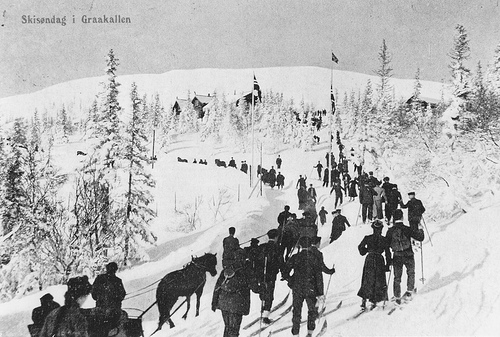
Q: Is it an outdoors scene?
A: Yes, it is outdoors.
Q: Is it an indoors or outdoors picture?
A: It is outdoors.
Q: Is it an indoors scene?
A: No, it is outdoors.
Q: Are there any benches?
A: No, there are no benches.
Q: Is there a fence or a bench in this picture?
A: No, there are no benches or fences.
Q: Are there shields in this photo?
A: No, there are no shields.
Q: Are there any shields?
A: No, there are no shields.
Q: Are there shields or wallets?
A: No, there are no shields or wallets.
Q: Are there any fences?
A: No, there are no fences.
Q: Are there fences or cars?
A: No, there are no fences or cars.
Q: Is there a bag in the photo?
A: Yes, there is a bag.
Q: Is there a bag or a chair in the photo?
A: Yes, there is a bag.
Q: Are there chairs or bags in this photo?
A: Yes, there is a bag.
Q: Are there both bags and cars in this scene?
A: No, there is a bag but no cars.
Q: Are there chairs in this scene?
A: No, there are no chairs.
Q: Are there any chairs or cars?
A: No, there are no chairs or cars.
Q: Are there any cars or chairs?
A: No, there are no chairs or cars.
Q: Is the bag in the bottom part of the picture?
A: Yes, the bag is in the bottom of the image.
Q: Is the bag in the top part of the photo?
A: No, the bag is in the bottom of the image.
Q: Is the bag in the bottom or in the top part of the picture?
A: The bag is in the bottom of the image.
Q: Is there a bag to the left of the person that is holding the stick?
A: Yes, there is a bag to the left of the person.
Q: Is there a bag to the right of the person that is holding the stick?
A: No, the bag is to the left of the person.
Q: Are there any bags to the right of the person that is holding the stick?
A: No, the bag is to the left of the person.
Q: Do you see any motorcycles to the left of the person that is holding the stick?
A: No, there is a bag to the left of the person.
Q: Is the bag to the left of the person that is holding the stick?
A: Yes, the bag is to the left of the person.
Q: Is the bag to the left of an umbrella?
A: No, the bag is to the left of the person.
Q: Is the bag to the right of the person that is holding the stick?
A: No, the bag is to the left of the person.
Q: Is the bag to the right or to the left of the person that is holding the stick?
A: The bag is to the left of the person.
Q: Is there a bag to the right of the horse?
A: Yes, there is a bag to the right of the horse.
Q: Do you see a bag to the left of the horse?
A: No, the bag is to the right of the horse.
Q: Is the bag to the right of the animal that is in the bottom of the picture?
A: Yes, the bag is to the right of the horse.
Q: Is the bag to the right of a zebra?
A: No, the bag is to the right of the horse.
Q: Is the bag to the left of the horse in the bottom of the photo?
A: No, the bag is to the right of the horse.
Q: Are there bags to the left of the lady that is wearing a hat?
A: Yes, there is a bag to the left of the lady.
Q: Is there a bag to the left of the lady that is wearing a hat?
A: Yes, there is a bag to the left of the lady.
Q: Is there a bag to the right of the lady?
A: No, the bag is to the left of the lady.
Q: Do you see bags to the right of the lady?
A: No, the bag is to the left of the lady.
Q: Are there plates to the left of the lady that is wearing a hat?
A: No, there is a bag to the left of the lady.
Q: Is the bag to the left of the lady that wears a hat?
A: Yes, the bag is to the left of the lady.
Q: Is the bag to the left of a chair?
A: No, the bag is to the left of the lady.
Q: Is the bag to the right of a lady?
A: No, the bag is to the left of a lady.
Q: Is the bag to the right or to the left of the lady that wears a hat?
A: The bag is to the left of the lady.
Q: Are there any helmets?
A: No, there are no helmets.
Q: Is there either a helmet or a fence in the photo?
A: No, there are no helmets or fences.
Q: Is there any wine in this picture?
A: No, there is no wine.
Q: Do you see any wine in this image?
A: No, there is no wine.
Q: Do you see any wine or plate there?
A: No, there are no wine or plates.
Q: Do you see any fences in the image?
A: No, there are no fences.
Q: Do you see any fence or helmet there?
A: No, there are no fences or helmets.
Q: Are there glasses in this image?
A: No, there are no glasses.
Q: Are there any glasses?
A: No, there are no glasses.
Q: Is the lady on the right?
A: Yes, the lady is on the right of the image.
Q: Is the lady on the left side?
A: No, the lady is on the right of the image.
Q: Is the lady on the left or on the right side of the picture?
A: The lady is on the right of the image.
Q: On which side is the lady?
A: The lady is on the right of the image.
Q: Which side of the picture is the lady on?
A: The lady is on the right of the image.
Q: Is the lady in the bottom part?
A: Yes, the lady is in the bottom of the image.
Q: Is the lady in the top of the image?
A: No, the lady is in the bottom of the image.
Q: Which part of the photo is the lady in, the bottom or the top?
A: The lady is in the bottom of the image.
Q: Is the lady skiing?
A: Yes, the lady is skiing.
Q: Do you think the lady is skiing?
A: Yes, the lady is skiing.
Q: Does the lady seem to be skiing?
A: Yes, the lady is skiing.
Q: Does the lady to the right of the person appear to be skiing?
A: Yes, the lady is skiing.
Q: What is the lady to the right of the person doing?
A: The lady is skiing.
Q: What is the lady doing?
A: The lady is skiing.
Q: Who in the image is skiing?
A: The lady is skiing.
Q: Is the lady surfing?
A: No, the lady is skiing.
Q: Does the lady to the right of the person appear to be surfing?
A: No, the lady is skiing.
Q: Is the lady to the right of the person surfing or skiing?
A: The lady is skiing.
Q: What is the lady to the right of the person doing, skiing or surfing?
A: The lady is skiing.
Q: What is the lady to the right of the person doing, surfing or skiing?
A: The lady is skiing.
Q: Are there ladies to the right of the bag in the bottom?
A: Yes, there is a lady to the right of the bag.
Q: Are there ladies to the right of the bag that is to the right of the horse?
A: Yes, there is a lady to the right of the bag.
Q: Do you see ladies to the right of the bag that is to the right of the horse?
A: Yes, there is a lady to the right of the bag.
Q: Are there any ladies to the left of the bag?
A: No, the lady is to the right of the bag.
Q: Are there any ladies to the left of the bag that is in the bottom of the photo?
A: No, the lady is to the right of the bag.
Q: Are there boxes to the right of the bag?
A: No, there is a lady to the right of the bag.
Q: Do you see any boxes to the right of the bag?
A: No, there is a lady to the right of the bag.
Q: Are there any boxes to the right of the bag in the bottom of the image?
A: No, there is a lady to the right of the bag.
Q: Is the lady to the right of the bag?
A: Yes, the lady is to the right of the bag.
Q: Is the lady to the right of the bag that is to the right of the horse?
A: Yes, the lady is to the right of the bag.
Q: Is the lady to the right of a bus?
A: No, the lady is to the right of the bag.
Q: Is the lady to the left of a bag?
A: No, the lady is to the right of a bag.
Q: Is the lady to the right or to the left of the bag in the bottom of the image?
A: The lady is to the right of the bag.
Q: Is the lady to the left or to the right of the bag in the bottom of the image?
A: The lady is to the right of the bag.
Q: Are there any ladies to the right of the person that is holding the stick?
A: Yes, there is a lady to the right of the person.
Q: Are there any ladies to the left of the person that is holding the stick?
A: No, the lady is to the right of the person.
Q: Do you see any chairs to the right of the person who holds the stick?
A: No, there is a lady to the right of the person.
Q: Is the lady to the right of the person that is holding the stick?
A: Yes, the lady is to the right of the person.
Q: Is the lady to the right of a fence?
A: No, the lady is to the right of the person.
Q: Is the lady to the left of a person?
A: No, the lady is to the right of a person.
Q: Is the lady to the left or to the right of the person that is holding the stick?
A: The lady is to the right of the person.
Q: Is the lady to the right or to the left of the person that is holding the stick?
A: The lady is to the right of the person.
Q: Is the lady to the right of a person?
A: Yes, the lady is to the right of a person.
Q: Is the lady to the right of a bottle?
A: No, the lady is to the right of a person.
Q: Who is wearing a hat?
A: The lady is wearing a hat.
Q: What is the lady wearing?
A: The lady is wearing a hat.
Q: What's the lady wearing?
A: The lady is wearing a hat.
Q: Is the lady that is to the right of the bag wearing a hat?
A: Yes, the lady is wearing a hat.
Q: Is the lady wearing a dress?
A: No, the lady is wearing a hat.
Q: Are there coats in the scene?
A: Yes, there is a coat.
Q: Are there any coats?
A: Yes, there is a coat.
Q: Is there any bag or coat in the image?
A: Yes, there is a coat.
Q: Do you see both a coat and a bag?
A: Yes, there are both a coat and a bag.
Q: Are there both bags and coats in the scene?
A: Yes, there are both a coat and a bag.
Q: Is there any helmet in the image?
A: No, there are no helmets.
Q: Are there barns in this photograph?
A: No, there are no barns.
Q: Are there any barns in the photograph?
A: No, there are no barns.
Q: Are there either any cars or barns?
A: No, there are no barns or cars.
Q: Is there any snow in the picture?
A: Yes, there is snow.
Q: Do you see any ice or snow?
A: Yes, there is snow.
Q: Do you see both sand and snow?
A: No, there is snow but no sand.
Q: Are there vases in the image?
A: No, there are no vases.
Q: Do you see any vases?
A: No, there are no vases.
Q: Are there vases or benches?
A: No, there are no vases or benches.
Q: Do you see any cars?
A: No, there are no cars.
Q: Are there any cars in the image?
A: No, there are no cars.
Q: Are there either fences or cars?
A: No, there are no cars or fences.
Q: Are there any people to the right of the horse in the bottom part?
A: Yes, there is a person to the right of the horse.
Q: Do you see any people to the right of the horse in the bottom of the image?
A: Yes, there is a person to the right of the horse.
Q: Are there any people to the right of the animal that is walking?
A: Yes, there is a person to the right of the horse.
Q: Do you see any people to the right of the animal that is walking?
A: Yes, there is a person to the right of the horse.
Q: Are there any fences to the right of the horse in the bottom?
A: No, there is a person to the right of the horse.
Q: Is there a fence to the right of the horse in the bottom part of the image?
A: No, there is a person to the right of the horse.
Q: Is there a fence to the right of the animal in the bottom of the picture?
A: No, there is a person to the right of the horse.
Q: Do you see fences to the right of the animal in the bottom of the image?
A: No, there is a person to the right of the horse.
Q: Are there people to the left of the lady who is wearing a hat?
A: Yes, there is a person to the left of the lady.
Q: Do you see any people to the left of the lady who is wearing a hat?
A: Yes, there is a person to the left of the lady.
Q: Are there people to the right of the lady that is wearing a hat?
A: No, the person is to the left of the lady.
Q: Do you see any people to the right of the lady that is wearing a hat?
A: No, the person is to the left of the lady.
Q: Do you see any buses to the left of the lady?
A: No, there is a person to the left of the lady.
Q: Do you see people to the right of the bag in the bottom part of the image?
A: Yes, there is a person to the right of the bag.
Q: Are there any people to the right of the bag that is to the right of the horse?
A: Yes, there is a person to the right of the bag.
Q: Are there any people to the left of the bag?
A: No, the person is to the right of the bag.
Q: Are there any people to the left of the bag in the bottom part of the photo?
A: No, the person is to the right of the bag.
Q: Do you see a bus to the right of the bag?
A: No, there is a person to the right of the bag.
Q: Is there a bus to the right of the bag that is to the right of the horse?
A: No, there is a person to the right of the bag.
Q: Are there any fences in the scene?
A: No, there are no fences.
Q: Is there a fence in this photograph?
A: No, there are no fences.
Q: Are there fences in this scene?
A: No, there are no fences.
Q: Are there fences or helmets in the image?
A: No, there are no fences or helmets.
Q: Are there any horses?
A: Yes, there is a horse.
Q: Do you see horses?
A: Yes, there is a horse.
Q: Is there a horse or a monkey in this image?
A: Yes, there is a horse.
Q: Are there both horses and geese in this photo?
A: No, there is a horse but no geese.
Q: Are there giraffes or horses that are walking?
A: Yes, the horse is walking.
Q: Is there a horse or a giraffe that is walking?
A: Yes, the horse is walking.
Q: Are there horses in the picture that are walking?
A: Yes, there is a horse that is walking.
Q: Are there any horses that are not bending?
A: Yes, there is a horse that is walking.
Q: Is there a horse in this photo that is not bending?
A: Yes, there is a horse that is walking.